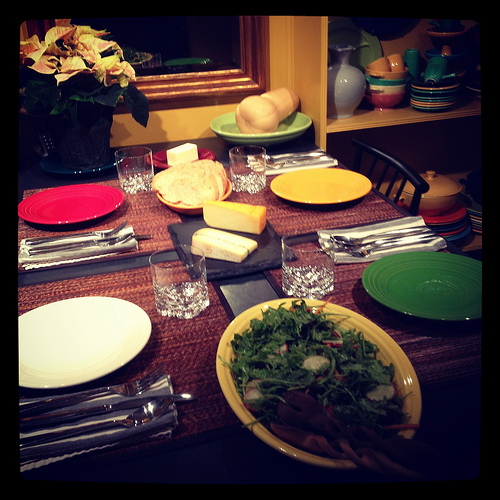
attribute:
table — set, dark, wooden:
[18, 135, 483, 484]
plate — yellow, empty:
[271, 168, 373, 205]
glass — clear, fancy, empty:
[229, 145, 268, 194]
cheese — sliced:
[192, 228, 259, 264]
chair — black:
[351, 137, 430, 217]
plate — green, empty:
[361, 250, 483, 321]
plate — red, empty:
[17, 184, 124, 224]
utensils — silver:
[330, 228, 439, 258]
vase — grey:
[327, 43, 365, 119]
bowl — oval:
[215, 297, 422, 470]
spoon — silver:
[330, 224, 430, 242]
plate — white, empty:
[18, 295, 153, 388]